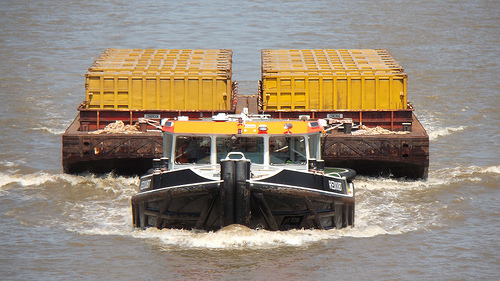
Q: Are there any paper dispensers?
A: No, there are no paper dispensers.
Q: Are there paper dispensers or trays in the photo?
A: No, there are no paper dispensers or trays.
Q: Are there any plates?
A: No, there are no plates.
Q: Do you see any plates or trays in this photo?
A: No, there are no plates or trays.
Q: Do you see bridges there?
A: Yes, there is a bridge.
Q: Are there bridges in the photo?
A: Yes, there is a bridge.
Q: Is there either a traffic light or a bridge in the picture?
A: Yes, there is a bridge.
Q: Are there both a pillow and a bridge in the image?
A: No, there is a bridge but no pillows.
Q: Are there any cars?
A: No, there are no cars.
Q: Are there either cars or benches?
A: No, there are no cars or benches.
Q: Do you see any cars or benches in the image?
A: No, there are no cars or benches.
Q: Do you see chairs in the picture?
A: No, there are no chairs.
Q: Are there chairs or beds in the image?
A: No, there are no chairs or beds.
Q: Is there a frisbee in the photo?
A: No, there are no frisbees.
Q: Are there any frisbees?
A: No, there are no frisbees.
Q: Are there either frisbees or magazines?
A: No, there are no frisbees or magazines.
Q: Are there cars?
A: No, there are no cars.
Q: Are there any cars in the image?
A: No, there are no cars.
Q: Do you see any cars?
A: No, there are no cars.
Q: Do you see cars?
A: No, there are no cars.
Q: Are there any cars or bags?
A: No, there are no cars or bags.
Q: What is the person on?
A: The person is on the deck.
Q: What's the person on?
A: The person is on the deck.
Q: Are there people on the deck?
A: Yes, there is a person on the deck.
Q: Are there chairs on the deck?
A: No, there is a person on the deck.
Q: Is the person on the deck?
A: Yes, the person is on the deck.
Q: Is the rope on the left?
A: Yes, the rope is on the left of the image.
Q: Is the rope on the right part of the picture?
A: No, the rope is on the left of the image.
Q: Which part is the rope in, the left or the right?
A: The rope is on the left of the image.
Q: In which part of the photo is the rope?
A: The rope is on the left of the image.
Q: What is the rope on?
A: The rope is on the deck.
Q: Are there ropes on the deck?
A: Yes, there is a rope on the deck.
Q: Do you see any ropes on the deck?
A: Yes, there is a rope on the deck.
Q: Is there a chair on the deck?
A: No, there is a rope on the deck.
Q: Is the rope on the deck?
A: Yes, the rope is on the deck.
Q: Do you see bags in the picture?
A: No, there are no bags.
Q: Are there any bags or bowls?
A: No, there are no bags or bowls.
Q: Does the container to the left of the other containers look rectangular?
A: Yes, the container is rectangular.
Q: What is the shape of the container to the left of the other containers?
A: The container is rectangular.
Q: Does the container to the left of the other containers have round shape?
A: No, the container is rectangular.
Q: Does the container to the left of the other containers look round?
A: No, the container is rectangular.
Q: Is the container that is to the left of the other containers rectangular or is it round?
A: The container is rectangular.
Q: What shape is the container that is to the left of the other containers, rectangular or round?
A: The container is rectangular.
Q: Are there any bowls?
A: No, there are no bowls.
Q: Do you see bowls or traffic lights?
A: No, there are no bowls or traffic lights.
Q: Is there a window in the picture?
A: Yes, there are windows.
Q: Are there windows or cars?
A: Yes, there are windows.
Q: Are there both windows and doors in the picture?
A: No, there are windows but no doors.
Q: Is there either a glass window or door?
A: Yes, there are glass windows.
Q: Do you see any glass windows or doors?
A: Yes, there are glass windows.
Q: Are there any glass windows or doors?
A: Yes, there are glass windows.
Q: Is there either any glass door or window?
A: Yes, there are glass windows.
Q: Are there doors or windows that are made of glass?
A: Yes, the windows are made of glass.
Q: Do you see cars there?
A: No, there are no cars.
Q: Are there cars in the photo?
A: No, there are no cars.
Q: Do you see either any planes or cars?
A: No, there are no cars or planes.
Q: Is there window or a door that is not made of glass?
A: No, there are windows but they are made of glass.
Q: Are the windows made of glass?
A: Yes, the windows are made of glass.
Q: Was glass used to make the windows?
A: Yes, the windows are made of glass.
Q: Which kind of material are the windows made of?
A: The windows are made of glass.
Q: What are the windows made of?
A: The windows are made of glass.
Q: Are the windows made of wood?
A: No, the windows are made of glass.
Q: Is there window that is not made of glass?
A: No, there are windows but they are made of glass.